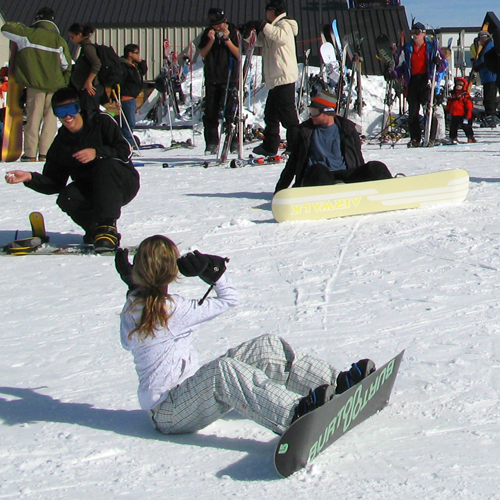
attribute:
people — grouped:
[3, 3, 496, 440]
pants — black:
[52, 158, 144, 230]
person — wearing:
[439, 74, 479, 145]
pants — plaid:
[146, 329, 346, 439]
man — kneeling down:
[4, 79, 145, 256]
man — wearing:
[266, 83, 407, 199]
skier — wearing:
[104, 233, 381, 445]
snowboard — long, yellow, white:
[266, 166, 477, 224]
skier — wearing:
[248, 4, 308, 164]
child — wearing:
[440, 71, 482, 146]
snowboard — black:
[274, 345, 411, 480]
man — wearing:
[392, 16, 448, 153]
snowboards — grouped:
[295, 38, 369, 133]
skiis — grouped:
[295, 38, 369, 133]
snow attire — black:
[62, 136, 128, 205]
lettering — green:
[302, 366, 409, 475]